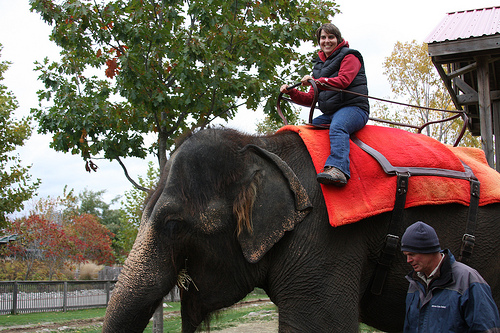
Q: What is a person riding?
A: An elephant.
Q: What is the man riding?
A: Elephant.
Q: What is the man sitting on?
A: Saddle.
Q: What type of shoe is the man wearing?
A: Boots.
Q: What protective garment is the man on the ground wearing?
A: Jacket.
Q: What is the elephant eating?
A: Hay.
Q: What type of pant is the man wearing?
A: Jeans.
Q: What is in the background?
A: Trees.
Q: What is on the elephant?
A: A red blanket.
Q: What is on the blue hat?
A: A black stripe.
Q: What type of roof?
A: Tin.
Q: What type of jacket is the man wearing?
A: A vest.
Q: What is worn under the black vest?
A: A red shirt.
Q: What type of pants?
A: Blue jeans.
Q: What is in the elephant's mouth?
A: Hay.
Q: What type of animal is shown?
A: Elephant.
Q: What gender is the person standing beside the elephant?
A: Male.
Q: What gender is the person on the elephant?
A: Female.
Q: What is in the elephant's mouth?
A: Straw.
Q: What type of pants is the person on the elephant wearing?
A: Jeans.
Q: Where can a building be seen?
A: Top right side.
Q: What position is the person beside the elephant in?
A: Standing.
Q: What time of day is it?
A: Daytime.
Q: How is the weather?
A: Clear and cold.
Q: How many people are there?
A: Two.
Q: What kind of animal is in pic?
A: Elephant.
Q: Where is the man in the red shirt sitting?
A: On the elephant's back.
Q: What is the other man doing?
A: Walking beside the elephant.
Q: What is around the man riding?
A: A frame.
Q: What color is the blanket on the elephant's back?
A: Red.